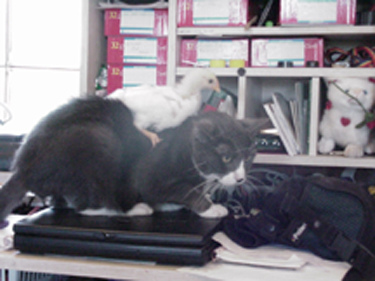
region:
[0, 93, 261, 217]
Black and white cat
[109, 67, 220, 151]
Orange and white durck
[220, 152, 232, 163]
yellow and black eye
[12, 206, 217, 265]
solid black lat top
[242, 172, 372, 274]
Black and blue backpack on table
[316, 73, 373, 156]
Red and white teddy bear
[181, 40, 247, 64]
Red and white boxes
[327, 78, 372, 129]
Red and green rose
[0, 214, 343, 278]
messy white table top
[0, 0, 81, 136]
Glare coming through the window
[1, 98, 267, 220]
A gray cat has white feet.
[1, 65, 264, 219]
A chicken is on the back of a cat.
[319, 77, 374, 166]
A white and pink stuffed animal is on a shelf.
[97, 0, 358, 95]
Pink, white and blue boxes are on shelves.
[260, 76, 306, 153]
Papers are stuffed in a nook.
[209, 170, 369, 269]
A white notebook is under the bag.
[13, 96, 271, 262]
A cat is sitting on a brown folded surface.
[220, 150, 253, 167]
An animal has green eyes with large black pupils.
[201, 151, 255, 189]
A cat has white fur on its' face.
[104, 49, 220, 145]
A white chicken has a black eye and orange beak and feet.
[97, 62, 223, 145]
A small white duck sitting atop a cat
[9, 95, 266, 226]
A black and white cat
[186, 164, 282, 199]
Long white whiskers on the cat's face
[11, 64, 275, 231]
Two animals sitting on a laptop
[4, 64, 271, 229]
The cat is carrying the duck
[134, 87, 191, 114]
Short white feathers on the duck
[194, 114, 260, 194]
The cat looks scared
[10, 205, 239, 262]
A thick black laptop beneath the animals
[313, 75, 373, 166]
A stuffed white animal in a cubby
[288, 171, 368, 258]
A green and black bag on the table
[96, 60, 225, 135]
duck is laying on top of the cat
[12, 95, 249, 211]
cat is sitting on top of a box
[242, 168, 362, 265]
bag is laying on the table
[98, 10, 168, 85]
boxes are stacked on the shelf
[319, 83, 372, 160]
stuffed animal on the shelf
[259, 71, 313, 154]
books on the shelf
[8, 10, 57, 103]
light shining through the window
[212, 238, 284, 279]
notebook on the table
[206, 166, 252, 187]
cat has a white nose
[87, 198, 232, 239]
cat's feet are white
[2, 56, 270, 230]
Black and white cat with duck on back.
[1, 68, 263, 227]
Black cat with long whiskers with duck on back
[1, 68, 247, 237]
Black cat with white paws with duck on back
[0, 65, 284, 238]
Duck with black eyes riding cats back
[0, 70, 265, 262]
Duck with orange beak riding cats back.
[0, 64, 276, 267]
Black and white cat sitting on top of laptop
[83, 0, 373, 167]
White cubicle holding various books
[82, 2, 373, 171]
White cubicle holding pink and multi-colored boxes.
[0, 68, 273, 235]
Cat with black tipped nose sitting on laptop.